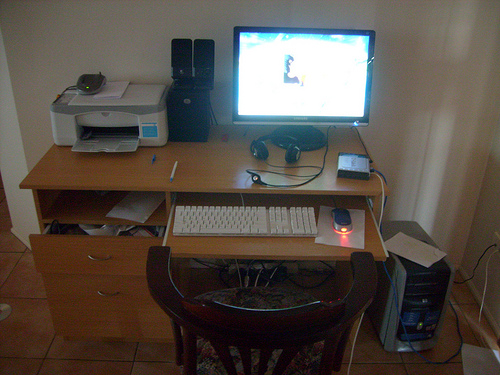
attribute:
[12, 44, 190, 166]
printer — computer, white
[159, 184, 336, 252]
keyboard — white, computer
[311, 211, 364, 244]
mouse — wireless, computer, gray, silver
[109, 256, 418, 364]
chair — wooden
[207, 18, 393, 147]
monitor — computer, glowing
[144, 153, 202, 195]
pen — white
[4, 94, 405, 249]
desk — wooden, top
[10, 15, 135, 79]
wall — white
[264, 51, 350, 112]
screen — bright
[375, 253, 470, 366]
computer — black, sitting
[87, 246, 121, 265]
handle — metal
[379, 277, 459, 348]
tower — computer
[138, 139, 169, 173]
cap — blue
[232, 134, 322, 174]
headphone — black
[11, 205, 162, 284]
drawer — open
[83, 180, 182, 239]
paper — slot